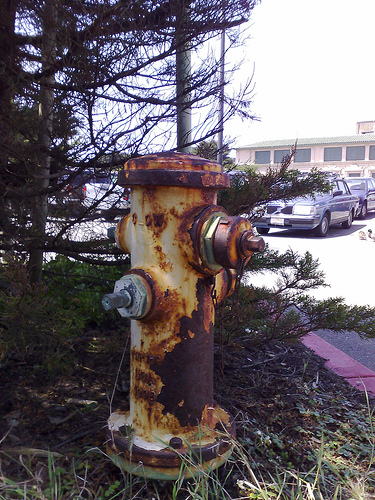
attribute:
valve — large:
[202, 207, 265, 274]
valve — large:
[100, 270, 150, 319]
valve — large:
[102, 213, 133, 252]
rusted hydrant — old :
[100, 152, 265, 482]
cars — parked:
[249, 171, 373, 237]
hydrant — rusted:
[102, 152, 265, 480]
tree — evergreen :
[9, 13, 111, 326]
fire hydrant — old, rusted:
[101, 146, 270, 493]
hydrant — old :
[101, 150, 234, 476]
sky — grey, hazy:
[235, 20, 361, 125]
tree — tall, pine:
[2, 3, 267, 380]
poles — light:
[169, 4, 227, 190]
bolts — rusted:
[108, 399, 228, 447]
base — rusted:
[105, 398, 242, 477]